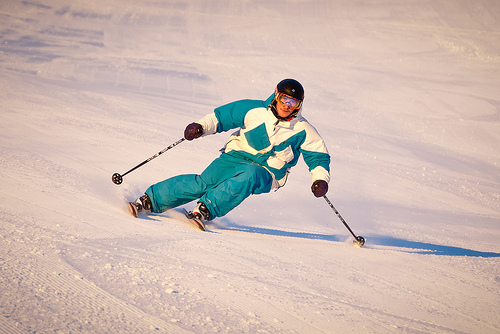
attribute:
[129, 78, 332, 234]
man — skiing, moving, ski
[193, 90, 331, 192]
jacket — white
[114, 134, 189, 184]
poles — black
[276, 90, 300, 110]
goggles — clear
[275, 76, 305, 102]
helmet — black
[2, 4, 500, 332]
ground — snow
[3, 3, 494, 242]
snow — white, smooth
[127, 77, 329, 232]
woman — side, skiig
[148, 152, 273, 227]
trousers — emerald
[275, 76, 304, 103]
hat — black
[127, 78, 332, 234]
skier — leaning, blue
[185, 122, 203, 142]
gloves — dark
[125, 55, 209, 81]
mark — lots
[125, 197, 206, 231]
skis — attached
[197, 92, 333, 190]
coat — thick